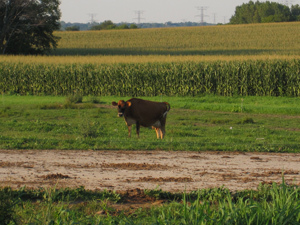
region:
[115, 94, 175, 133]
this is a cow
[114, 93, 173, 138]
the cow is standing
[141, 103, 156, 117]
the cow is brown in color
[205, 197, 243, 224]
these are the grass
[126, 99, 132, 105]
this is the ear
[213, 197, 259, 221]
the grass are green in color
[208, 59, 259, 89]
this is a maize plantation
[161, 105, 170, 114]
this is the tail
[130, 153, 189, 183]
the place is muddy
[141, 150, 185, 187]
the mud is brown in color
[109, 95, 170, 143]
a cow standing alone in a field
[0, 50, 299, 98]
tall crops growing in a field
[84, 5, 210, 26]
electricity pylons in the background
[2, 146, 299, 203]
a wet muddy track on a field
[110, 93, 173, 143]
a brown cow faces the camera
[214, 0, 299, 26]
tall trees behind a field of crops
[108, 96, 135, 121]
the sun is catching the cows head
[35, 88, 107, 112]
shrubs growing in a field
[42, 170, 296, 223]
tall green tufts in the foreground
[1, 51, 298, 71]
yellow ripened tops of crops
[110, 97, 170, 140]
One brown cow standing in grass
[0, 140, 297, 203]
A path of mud in between grass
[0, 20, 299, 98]
Large fields of green cord with yellow tassles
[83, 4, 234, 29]
Power lines and towers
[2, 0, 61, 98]
Tall green tree next to a corn field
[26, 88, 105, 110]
Clumps of weeds and grass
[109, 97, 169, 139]
Brown and white cow with a black nose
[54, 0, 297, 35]
Rows of trees beyond a corn field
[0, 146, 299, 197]
Thick wet brown mud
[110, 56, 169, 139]
Cow standing beside a corn field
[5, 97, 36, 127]
this is the grass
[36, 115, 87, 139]
the grass is green in color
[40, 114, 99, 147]
the grass is short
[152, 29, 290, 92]
these are maize plants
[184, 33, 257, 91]
the maize plants are green in color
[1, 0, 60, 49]
this is a tree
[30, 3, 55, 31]
the leaves are green in color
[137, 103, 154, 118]
the fur is brown in color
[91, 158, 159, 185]
the ground is brown in color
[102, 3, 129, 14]
this is the sky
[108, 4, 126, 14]
the sky is blue in color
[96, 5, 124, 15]
the sky is full of clouds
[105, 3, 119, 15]
the clouds are white in color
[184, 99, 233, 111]
this is the grass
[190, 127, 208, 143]
the grass is green in color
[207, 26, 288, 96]
these are some maize plants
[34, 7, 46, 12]
the leaves are green in color